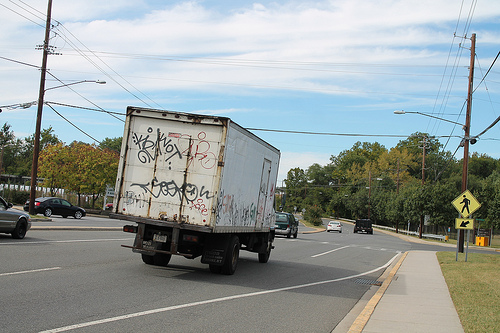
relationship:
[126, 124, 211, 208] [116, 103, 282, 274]
graffiti on truck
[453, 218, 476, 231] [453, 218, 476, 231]
sign has sign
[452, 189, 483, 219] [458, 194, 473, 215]
sign has figure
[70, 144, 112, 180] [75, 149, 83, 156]
tree has leaves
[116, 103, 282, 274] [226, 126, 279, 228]
truck has side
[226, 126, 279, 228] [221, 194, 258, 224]
side has graffiti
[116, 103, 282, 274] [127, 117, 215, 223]
truck has back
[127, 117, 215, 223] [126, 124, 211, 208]
back has graffiti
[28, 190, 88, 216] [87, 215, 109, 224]
car turning on road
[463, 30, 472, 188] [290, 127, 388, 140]
pole has power lines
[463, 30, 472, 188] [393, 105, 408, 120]
pole has streetlight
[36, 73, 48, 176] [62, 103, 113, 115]
pole has powerlines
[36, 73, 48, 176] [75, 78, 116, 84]
pole has streetlight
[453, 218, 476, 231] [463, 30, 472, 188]
sign on pole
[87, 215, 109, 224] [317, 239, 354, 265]
road has line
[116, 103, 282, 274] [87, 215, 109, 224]
truck on road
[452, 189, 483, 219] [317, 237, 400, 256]
sign indicates crosswalk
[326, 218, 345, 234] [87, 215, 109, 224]
car on road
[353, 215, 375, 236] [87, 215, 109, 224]
car on road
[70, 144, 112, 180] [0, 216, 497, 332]
tree by road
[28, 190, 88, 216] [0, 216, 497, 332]
car on road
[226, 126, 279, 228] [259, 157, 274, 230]
side has door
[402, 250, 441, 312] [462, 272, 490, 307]
sidewalk next to grass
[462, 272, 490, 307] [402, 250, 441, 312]
grass next to sidewalk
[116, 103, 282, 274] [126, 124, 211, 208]
truck has graffiti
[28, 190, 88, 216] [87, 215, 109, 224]
car on road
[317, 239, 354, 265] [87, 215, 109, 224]
line on road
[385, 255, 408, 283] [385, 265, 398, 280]
curb has line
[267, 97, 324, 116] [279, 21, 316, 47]
sky has clouds